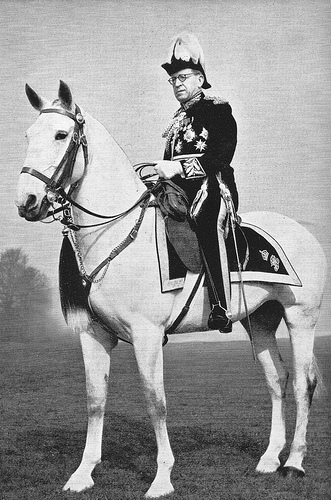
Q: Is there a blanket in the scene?
A: Yes, there is a blanket.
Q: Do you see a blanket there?
A: Yes, there is a blanket.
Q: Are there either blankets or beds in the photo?
A: Yes, there is a blanket.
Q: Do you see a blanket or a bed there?
A: Yes, there is a blanket.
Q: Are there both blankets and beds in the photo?
A: No, there is a blanket but no beds.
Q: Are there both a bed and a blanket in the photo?
A: No, there is a blanket but no beds.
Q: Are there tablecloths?
A: No, there are no tablecloths.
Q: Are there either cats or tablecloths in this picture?
A: No, there are no tablecloths or cats.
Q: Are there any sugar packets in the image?
A: No, there are no sugar packets.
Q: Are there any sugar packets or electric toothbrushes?
A: No, there are no sugar packets or electric toothbrushes.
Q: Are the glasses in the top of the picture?
A: Yes, the glasses are in the top of the image.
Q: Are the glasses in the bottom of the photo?
A: No, the glasses are in the top of the image.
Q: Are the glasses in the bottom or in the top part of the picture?
A: The glasses are in the top of the image.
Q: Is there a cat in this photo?
A: No, there are no cats.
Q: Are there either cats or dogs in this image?
A: No, there are no cats or dogs.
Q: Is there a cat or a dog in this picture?
A: No, there are no cats or dogs.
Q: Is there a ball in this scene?
A: No, there are no balls.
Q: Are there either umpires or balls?
A: No, there are no balls or umpires.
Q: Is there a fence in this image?
A: No, there are no fences.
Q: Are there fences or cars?
A: No, there are no fences or cars.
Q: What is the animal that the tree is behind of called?
A: The animal is a horse.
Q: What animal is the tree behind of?
A: The tree is behind the horse.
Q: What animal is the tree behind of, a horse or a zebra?
A: The tree is behind a horse.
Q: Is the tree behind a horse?
A: Yes, the tree is behind a horse.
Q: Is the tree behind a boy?
A: No, the tree is behind a horse.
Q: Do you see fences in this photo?
A: No, there are no fences.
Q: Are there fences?
A: No, there are no fences.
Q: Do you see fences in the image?
A: No, there are no fences.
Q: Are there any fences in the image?
A: No, there are no fences.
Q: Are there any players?
A: No, there are no players.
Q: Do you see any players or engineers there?
A: No, there are no players or engineers.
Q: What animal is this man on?
A: The man is on the horse.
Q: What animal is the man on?
A: The man is on the horse.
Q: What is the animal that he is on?
A: The animal is a horse.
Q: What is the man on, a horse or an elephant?
A: The man is on a horse.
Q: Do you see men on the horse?
A: Yes, there is a man on the horse.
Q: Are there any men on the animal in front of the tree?
A: Yes, there is a man on the horse.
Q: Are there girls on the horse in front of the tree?
A: No, there is a man on the horse.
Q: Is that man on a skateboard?
A: No, the man is on the horse.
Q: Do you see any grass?
A: Yes, there is grass.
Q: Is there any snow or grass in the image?
A: Yes, there is grass.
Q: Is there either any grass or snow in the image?
A: Yes, there is grass.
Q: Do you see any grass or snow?
A: Yes, there is grass.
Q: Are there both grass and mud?
A: No, there is grass but no mud.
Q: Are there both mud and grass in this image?
A: No, there is grass but no mud.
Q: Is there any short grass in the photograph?
A: Yes, there is short grass.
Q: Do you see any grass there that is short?
A: Yes, there is grass that is short.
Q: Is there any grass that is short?
A: Yes, there is grass that is short.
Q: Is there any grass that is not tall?
A: Yes, there is short grass.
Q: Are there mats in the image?
A: No, there are no mats.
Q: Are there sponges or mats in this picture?
A: No, there are no mats or sponges.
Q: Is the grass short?
A: Yes, the grass is short.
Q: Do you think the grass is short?
A: Yes, the grass is short.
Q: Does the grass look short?
A: Yes, the grass is short.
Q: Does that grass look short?
A: Yes, the grass is short.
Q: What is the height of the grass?
A: The grass is short.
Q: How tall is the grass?
A: The grass is short.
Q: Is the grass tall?
A: No, the grass is short.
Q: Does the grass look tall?
A: No, the grass is short.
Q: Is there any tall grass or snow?
A: No, there is grass but it is short.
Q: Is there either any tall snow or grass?
A: No, there is grass but it is short.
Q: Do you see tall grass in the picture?
A: No, there is grass but it is short.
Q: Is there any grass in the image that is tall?
A: No, there is grass but it is short.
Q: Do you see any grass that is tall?
A: No, there is grass but it is short.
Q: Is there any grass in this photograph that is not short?
A: No, there is grass but it is short.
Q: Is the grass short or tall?
A: The grass is short.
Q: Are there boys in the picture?
A: No, there are no boys.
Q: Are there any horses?
A: Yes, there is a horse.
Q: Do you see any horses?
A: Yes, there is a horse.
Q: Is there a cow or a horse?
A: Yes, there is a horse.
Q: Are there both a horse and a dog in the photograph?
A: No, there is a horse but no dogs.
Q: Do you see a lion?
A: No, there are no lions.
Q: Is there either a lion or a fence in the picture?
A: No, there are no lions or fences.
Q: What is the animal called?
A: The animal is a horse.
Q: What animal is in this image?
A: The animal is a horse.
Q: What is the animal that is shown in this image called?
A: The animal is a horse.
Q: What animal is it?
A: The animal is a horse.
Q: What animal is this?
A: This is a horse.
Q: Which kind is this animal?
A: This is a horse.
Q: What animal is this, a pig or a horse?
A: This is a horse.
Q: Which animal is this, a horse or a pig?
A: This is a horse.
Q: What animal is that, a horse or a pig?
A: That is a horse.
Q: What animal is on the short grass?
A: The horse is on the grass.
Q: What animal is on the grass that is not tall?
A: The animal is a horse.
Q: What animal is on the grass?
A: The animal is a horse.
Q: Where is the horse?
A: The horse is on the grass.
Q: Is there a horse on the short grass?
A: Yes, there is a horse on the grass.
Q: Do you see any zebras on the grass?
A: No, there is a horse on the grass.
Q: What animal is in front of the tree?
A: The horse is in front of the tree.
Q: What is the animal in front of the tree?
A: The animal is a horse.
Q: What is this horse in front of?
A: The horse is in front of the tree.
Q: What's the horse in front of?
A: The horse is in front of the tree.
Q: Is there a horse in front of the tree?
A: Yes, there is a horse in front of the tree.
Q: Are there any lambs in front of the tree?
A: No, there is a horse in front of the tree.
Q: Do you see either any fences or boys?
A: No, there are no boys or fences.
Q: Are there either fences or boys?
A: No, there are no boys or fences.